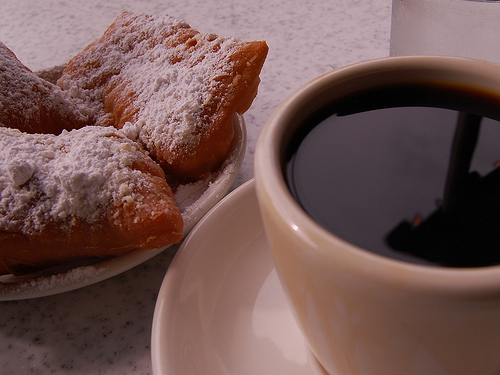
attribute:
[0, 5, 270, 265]
bread items — three, pieces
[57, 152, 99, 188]
powdered sugar — powdered 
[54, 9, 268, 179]
pastry — powdered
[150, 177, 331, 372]
saucer — plate, white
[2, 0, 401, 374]
spots — black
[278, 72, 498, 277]
black coffee — black 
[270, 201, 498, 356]
brown cup — brown 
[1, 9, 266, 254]
pastry — brown 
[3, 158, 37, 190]
sugar — ball, powdered 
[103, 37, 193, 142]
powder — white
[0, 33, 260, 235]
treats — powdered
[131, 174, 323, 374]
plate — white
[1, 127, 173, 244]
powdered sugar — powdered 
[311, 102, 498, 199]
coffee — inside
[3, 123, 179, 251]
pastry — other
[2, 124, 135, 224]
topping — powder, sugar 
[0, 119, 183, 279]
pastry — powdered 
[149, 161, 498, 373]
saucer — small, circle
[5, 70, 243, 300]
plate — white 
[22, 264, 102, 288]
powdered sugar — powdered 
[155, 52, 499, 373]
coffee — placed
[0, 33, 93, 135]
pastry — powdered 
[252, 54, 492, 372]
cup — tan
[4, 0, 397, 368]
surface — marble 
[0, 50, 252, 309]
dish — white 